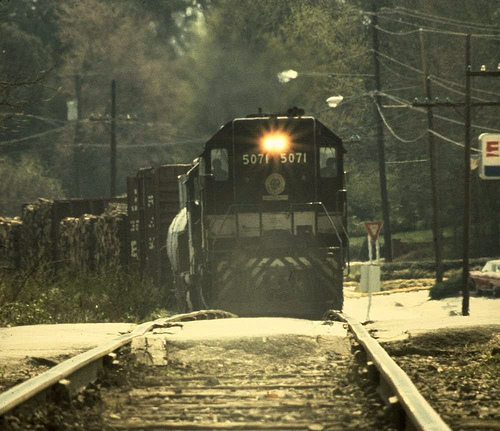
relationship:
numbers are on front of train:
[242, 151, 310, 165] [1, 106, 351, 317]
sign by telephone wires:
[478, 133, 500, 183] [366, 0, 499, 320]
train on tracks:
[1, 106, 351, 317] [1, 309, 460, 430]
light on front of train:
[258, 131, 293, 156] [1, 106, 351, 317]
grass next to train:
[2, 251, 180, 323] [1, 106, 351, 317]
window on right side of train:
[318, 146, 341, 182] [1, 106, 351, 317]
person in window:
[211, 158, 228, 181] [210, 147, 231, 185]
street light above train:
[277, 68, 299, 88] [1, 106, 351, 317]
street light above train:
[325, 94, 345, 110] [1, 106, 351, 317]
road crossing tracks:
[2, 294, 494, 354] [1, 309, 460, 430]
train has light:
[1, 106, 351, 317] [258, 131, 293, 156]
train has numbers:
[1, 106, 351, 317] [242, 151, 310, 165]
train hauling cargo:
[1, 106, 351, 317] [56, 203, 126, 284]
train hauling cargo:
[1, 106, 351, 317] [23, 199, 55, 291]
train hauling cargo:
[1, 106, 351, 317] [1, 215, 18, 281]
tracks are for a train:
[1, 309, 460, 430] [1, 106, 351, 317]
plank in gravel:
[123, 384, 337, 398] [13, 337, 402, 430]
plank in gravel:
[104, 419, 365, 430] [13, 337, 402, 430]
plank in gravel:
[146, 400, 348, 412] [13, 337, 402, 430]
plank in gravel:
[129, 336, 168, 367] [13, 337, 402, 430]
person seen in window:
[211, 158, 228, 181] [210, 147, 231, 185]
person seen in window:
[320, 155, 339, 178] [318, 146, 341, 182]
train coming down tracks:
[1, 106, 351, 317] [1, 309, 460, 430]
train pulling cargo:
[1, 106, 351, 317] [56, 203, 126, 284]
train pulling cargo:
[1, 106, 351, 317] [23, 199, 55, 291]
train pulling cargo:
[1, 106, 351, 317] [1, 215, 18, 281]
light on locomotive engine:
[258, 131, 293, 156] [185, 113, 351, 318]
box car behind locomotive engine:
[126, 162, 195, 300] [185, 113, 351, 318]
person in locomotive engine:
[211, 158, 228, 181] [185, 113, 351, 318]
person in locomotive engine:
[320, 155, 339, 178] [185, 113, 351, 318]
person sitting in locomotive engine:
[211, 158, 228, 181] [185, 113, 351, 318]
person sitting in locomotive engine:
[320, 155, 339, 178] [185, 113, 351, 318]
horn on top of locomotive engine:
[285, 105, 307, 118] [185, 113, 351, 318]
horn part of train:
[285, 105, 307, 118] [1, 106, 351, 317]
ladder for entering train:
[204, 204, 243, 292] [1, 106, 351, 317]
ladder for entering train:
[308, 194, 350, 284] [1, 106, 351, 317]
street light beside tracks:
[277, 68, 299, 88] [1, 309, 460, 430]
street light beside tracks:
[325, 94, 345, 110] [1, 309, 460, 430]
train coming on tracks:
[1, 106, 351, 317] [1, 309, 460, 430]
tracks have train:
[1, 309, 460, 430] [1, 106, 351, 317]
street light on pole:
[277, 68, 299, 88] [371, 6, 397, 252]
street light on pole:
[325, 94, 345, 110] [371, 6, 397, 252]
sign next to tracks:
[362, 220, 385, 243] [1, 309, 460, 430]